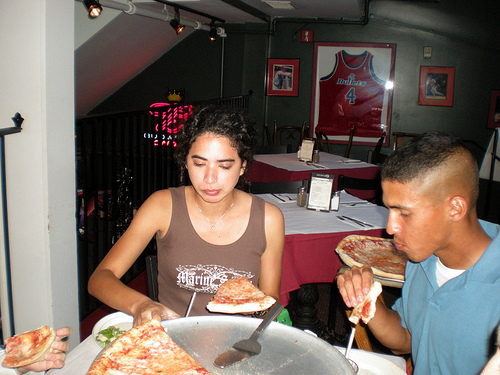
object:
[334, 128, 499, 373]
guy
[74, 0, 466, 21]
top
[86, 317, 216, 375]
pizza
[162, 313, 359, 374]
tray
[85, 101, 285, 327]
girl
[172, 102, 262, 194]
hair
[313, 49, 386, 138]
jersey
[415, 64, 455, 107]
picture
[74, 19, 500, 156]
wall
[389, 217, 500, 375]
shirt